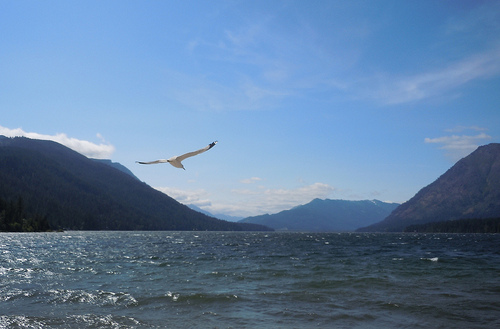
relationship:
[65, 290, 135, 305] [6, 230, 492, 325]
wave in water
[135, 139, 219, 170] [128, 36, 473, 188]
bird iin sky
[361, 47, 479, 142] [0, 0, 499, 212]
cloud in sky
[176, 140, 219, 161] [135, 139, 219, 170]
wing of bird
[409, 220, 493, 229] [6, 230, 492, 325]
shore line of water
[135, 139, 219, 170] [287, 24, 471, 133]
bird in air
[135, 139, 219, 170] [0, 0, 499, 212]
bird in sky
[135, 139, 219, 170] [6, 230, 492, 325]
bird flying above water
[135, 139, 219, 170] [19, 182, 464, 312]
bird flying above water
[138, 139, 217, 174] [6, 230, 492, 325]
bird flying over water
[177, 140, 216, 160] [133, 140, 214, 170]
wing of bird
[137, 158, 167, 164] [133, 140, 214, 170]
wing of bird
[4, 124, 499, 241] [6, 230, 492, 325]
mountains on water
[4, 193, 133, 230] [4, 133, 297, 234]
plants growing by mountain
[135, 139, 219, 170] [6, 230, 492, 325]
bird flying over water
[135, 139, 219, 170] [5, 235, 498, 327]
bird flying over ocean